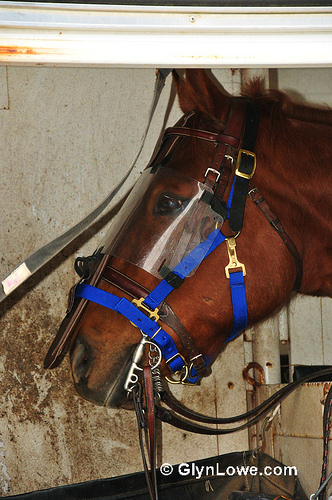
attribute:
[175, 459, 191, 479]
g — letter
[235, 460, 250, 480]
letter — w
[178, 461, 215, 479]
glyn — GlynLowe.com"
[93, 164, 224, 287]
plastic — clear